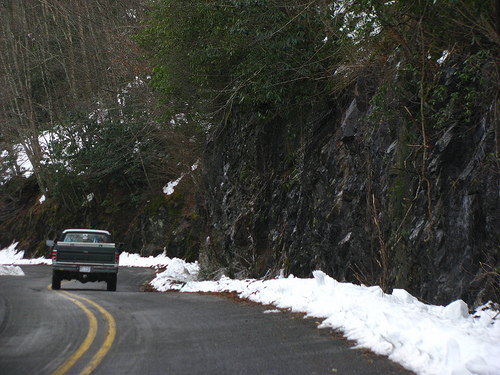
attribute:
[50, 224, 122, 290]
truck — driving, pickup, tan, running, grey, black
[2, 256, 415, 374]
road — wet, cleared, paved, grey, black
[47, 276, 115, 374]
lines — double, yellow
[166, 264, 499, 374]
cumpls — white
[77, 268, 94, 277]
license plate — white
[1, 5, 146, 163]
trees — hanging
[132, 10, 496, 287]
trees — rocky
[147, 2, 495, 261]
leaves — green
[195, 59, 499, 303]
rocks — black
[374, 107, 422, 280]
vines — hanging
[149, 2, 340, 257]
tree — growing, green, large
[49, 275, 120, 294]
tires — black